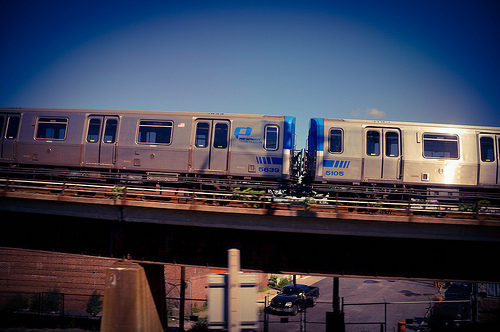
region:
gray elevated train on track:
[318, 99, 365, 206]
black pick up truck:
[258, 273, 298, 314]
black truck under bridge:
[264, 286, 322, 318]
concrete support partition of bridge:
[105, 279, 148, 317]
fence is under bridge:
[355, 299, 402, 323]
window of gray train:
[128, 118, 178, 153]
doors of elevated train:
[193, 123, 228, 168]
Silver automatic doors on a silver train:
[187, 115, 234, 175]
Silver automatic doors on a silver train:
[80, 110, 124, 170]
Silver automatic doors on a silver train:
[359, 121, 403, 183]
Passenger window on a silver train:
[132, 114, 177, 148]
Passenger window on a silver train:
[31, 113, 69, 142]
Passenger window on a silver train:
[420, 130, 464, 162]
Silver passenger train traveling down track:
[0, 100, 498, 211]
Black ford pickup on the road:
[267, 279, 323, 318]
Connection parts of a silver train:
[290, 145, 314, 203]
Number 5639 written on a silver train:
[256, 163, 283, 181]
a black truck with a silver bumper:
[266, 282, 321, 315]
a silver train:
[0, 109, 497, 199]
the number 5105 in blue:
[322, 168, 345, 178]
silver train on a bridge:
[3, 105, 498, 281]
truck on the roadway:
[258, 274, 453, 329]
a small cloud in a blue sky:
[2, 0, 498, 146]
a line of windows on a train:
[6, 108, 499, 164]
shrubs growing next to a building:
[1, 285, 102, 318]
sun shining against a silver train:
[398, 117, 474, 192]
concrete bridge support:
[99, 253, 164, 330]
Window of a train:
[118, 113, 188, 148]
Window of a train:
[24, 107, 72, 144]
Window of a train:
[324, 121, 355, 156]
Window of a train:
[411, 128, 478, 170]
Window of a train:
[475, 129, 498, 169]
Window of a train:
[384, 127, 401, 168]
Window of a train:
[362, 122, 379, 159]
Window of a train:
[212, 110, 235, 157]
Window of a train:
[188, 112, 210, 159]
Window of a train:
[82, 109, 124, 150]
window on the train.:
[140, 130, 169, 137]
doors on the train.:
[196, 122, 222, 158]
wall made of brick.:
[57, 268, 79, 282]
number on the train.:
[322, 170, 347, 180]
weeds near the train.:
[235, 188, 262, 204]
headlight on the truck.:
[284, 298, 291, 307]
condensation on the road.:
[397, 287, 415, 299]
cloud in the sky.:
[339, 96, 388, 116]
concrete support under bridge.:
[114, 266, 144, 326]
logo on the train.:
[235, 125, 262, 149]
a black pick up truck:
[266, 280, 322, 315]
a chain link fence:
[6, 288, 489, 330]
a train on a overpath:
[0, 103, 497, 330]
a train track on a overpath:
[4, 173, 496, 328]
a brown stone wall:
[4, 248, 186, 330]